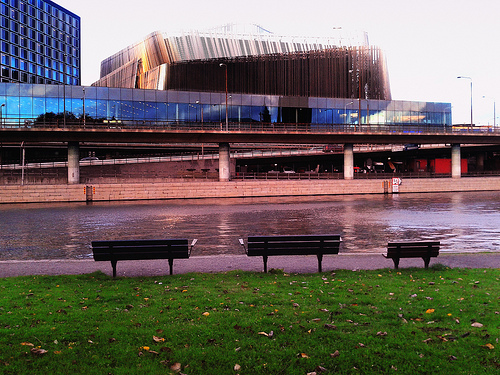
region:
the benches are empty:
[85, 223, 450, 278]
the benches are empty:
[56, 211, 481, 308]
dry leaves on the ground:
[87, 325, 197, 372]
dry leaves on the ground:
[300, 290, 405, 357]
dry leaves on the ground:
[143, 326, 244, 366]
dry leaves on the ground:
[424, 274, 490, 370]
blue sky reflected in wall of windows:
[1, 97, 452, 133]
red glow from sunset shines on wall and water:
[5, 180, 498, 257]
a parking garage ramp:
[11, 130, 498, 188]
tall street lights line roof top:
[0, 60, 487, 120]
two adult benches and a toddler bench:
[81, 230, 463, 279]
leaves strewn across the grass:
[6, 280, 498, 373]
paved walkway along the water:
[4, 248, 498, 270]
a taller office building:
[4, 4, 83, 88]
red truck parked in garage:
[404, 141, 474, 181]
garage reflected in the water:
[15, 199, 498, 246]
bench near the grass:
[376, 230, 448, 271]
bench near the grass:
[232, 230, 349, 272]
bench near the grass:
[91, 235, 200, 276]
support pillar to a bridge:
[62, 140, 81, 187]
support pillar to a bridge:
[214, 143, 234, 182]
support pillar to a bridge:
[340, 143, 359, 180]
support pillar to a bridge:
[447, 140, 463, 182]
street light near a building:
[451, 69, 477, 126]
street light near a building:
[479, 87, 498, 129]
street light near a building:
[214, 57, 236, 135]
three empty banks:
[91, 232, 440, 273]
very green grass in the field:
[14, 282, 493, 373]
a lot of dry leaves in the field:
[20, 287, 497, 364]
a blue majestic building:
[0, 0, 79, 82]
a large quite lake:
[20, 194, 495, 233]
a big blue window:
[1, 96, 281, 124]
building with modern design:
[101, 39, 385, 95]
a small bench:
[383, 239, 440, 272]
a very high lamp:
[455, 73, 477, 130]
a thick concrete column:
[218, 139, 230, 185]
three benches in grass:
[77, 226, 444, 284]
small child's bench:
[369, 226, 447, 272]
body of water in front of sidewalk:
[0, 187, 499, 257]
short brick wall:
[2, 175, 498, 204]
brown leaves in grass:
[82, 302, 237, 364]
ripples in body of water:
[199, 212, 286, 231]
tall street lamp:
[451, 68, 478, 127]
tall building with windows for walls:
[1, 0, 81, 87]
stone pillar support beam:
[62, 145, 86, 186]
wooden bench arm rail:
[229, 233, 249, 253]